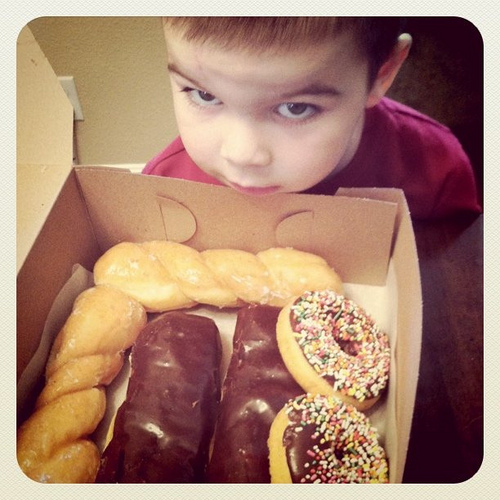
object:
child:
[140, 18, 483, 221]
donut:
[274, 289, 390, 412]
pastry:
[90, 236, 347, 315]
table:
[419, 206, 481, 474]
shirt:
[139, 96, 482, 223]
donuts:
[265, 393, 399, 499]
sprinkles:
[284, 393, 370, 423]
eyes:
[271, 99, 324, 124]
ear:
[364, 31, 415, 113]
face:
[166, 46, 373, 200]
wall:
[74, 19, 164, 150]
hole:
[325, 312, 368, 358]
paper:
[42, 264, 84, 334]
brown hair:
[157, 15, 360, 55]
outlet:
[55, 70, 87, 127]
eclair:
[205, 301, 304, 483]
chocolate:
[289, 290, 389, 399]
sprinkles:
[290, 289, 390, 402]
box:
[14, 163, 422, 483]